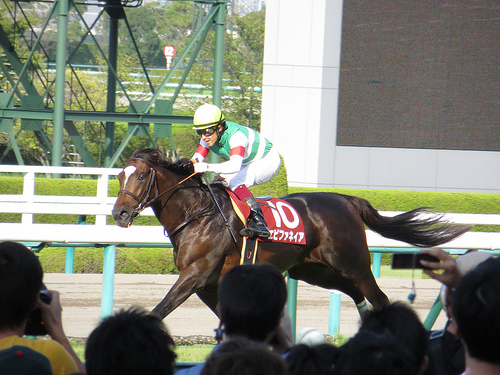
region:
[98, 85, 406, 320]
brown horse and jockey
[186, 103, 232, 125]
helmet on jockey's head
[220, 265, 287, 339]
spectator in the crowd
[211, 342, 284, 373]
spectator in the crowd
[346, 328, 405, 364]
spectator in the crowd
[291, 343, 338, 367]
spectator in the crowd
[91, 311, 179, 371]
spectator in the crowd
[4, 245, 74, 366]
spectator in the crowd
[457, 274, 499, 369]
spectator in the crowd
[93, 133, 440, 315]
the brown horse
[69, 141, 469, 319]
the horse is running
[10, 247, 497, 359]
a crowd of people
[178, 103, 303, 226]
the jockey on the horse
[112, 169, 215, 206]
the bridal on the horse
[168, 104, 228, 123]
the helmet on the jockey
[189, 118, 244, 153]
the jockey wearing goggles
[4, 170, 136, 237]
the fence beside the grass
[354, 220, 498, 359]
the person taking a picture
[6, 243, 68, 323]
the person taking a picture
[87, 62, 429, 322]
Man riding on horse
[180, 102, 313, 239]
The jokey is leaning forward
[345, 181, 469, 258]
The horse has a long tail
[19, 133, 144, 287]
Fence around the arena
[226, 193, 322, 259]
blanket with number on it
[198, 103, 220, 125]
Jockey wearing a helmet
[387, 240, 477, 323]
Person is holding a camera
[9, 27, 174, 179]
Water tower in the background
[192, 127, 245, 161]
Man is wearing goggles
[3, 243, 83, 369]
Person taking a video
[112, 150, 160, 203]
White spot on a horse's head.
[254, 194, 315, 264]
Horse seat has the number ten on it.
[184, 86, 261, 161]
The jockey helmet is white trimmed in black.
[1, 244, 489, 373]
The back of spectator heads are shown.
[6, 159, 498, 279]
Green grass shown through the fence.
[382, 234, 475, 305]
Spectator has camera in his hand.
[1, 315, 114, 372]
One spectator is wearing a yellow shirt.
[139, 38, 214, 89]
There is flag with the number 82 on it in the back.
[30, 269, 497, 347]
White gravel covers the horse path in the picture.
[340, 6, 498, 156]
A gray colored concrete wall.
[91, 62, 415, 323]
A horse and his jockey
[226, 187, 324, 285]
The horses number is ten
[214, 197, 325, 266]
The number is on a cloth that is red and white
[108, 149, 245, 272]
The horse is dark brown with white on its face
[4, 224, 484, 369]
Spectators at a horse race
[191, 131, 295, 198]
The jockey is wearing green white and red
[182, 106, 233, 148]
Jockey is wearing a yellow helmet and black goggles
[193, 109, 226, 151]
The jockey's helmet is yellow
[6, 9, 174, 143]
Green metal bleachers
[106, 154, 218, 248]
The horse is wearing a bridle